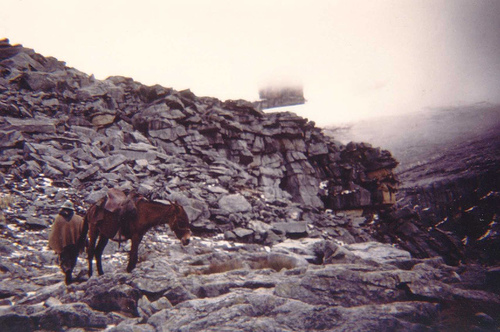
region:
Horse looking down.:
[151, 189, 213, 259]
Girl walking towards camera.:
[30, 186, 94, 287]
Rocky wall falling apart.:
[184, 104, 348, 199]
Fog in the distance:
[326, 67, 479, 163]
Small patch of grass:
[247, 243, 292, 278]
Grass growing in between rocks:
[178, 249, 253, 301]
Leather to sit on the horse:
[101, 172, 160, 216]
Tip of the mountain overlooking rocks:
[322, 99, 434, 221]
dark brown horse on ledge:
[70, 190, 190, 283]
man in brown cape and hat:
[46, 192, 89, 287]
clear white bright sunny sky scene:
[7, 0, 499, 127]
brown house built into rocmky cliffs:
[361, 156, 413, 203]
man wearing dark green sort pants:
[48, 246, 84, 274]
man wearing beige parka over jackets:
[46, 211, 91, 252]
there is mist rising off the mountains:
[30, 0, 495, 159]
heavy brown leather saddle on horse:
[98, 190, 140, 237]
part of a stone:
[255, 203, 281, 244]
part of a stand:
[129, 243, 185, 305]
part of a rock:
[312, 186, 321, 200]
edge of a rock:
[345, 172, 358, 238]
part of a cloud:
[392, 99, 407, 126]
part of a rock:
[263, 248, 294, 268]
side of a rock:
[278, 239, 297, 261]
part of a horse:
[136, 204, 141, 210]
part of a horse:
[176, 197, 185, 224]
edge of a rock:
[271, 192, 288, 219]